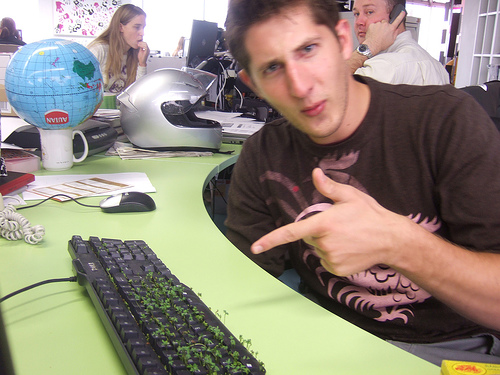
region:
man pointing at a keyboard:
[223, 0, 499, 362]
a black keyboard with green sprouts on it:
[68, 236, 266, 373]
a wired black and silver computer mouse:
[101, 192, 156, 213]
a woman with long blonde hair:
[90, 1, 148, 91]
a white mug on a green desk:
[36, 128, 88, 168]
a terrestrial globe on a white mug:
[3, 36, 105, 128]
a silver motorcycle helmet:
[117, 71, 226, 152]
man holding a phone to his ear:
[351, 0, 406, 43]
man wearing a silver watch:
[356, 43, 373, 59]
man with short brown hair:
[222, 0, 350, 135]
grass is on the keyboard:
[101, 260, 259, 370]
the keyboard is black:
[65, 233, 255, 373]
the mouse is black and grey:
[103, 190, 157, 215]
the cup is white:
[37, 129, 100, 166]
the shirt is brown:
[244, 129, 499, 320]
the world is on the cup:
[0, 32, 104, 123]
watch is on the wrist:
[353, 40, 380, 56]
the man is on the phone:
[363, 3, 450, 80]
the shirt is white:
[376, 43, 461, 87]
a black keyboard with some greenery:
[72, 237, 264, 366]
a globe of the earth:
[5, 39, 107, 128]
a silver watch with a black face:
[355, 40, 372, 56]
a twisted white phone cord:
[0, 205, 41, 245]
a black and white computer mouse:
[100, 190, 157, 212]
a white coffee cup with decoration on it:
[40, 128, 87, 171]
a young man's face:
[236, 0, 355, 135]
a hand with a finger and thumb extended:
[253, 168, 389, 276]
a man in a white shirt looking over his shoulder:
[353, 0, 446, 84]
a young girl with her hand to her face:
[93, 1, 148, 88]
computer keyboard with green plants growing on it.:
[62, 233, 267, 373]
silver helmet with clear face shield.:
[116, 65, 222, 149]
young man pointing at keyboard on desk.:
[222, 1, 497, 363]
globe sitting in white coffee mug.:
[5, 37, 102, 131]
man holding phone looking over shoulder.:
[352, 0, 450, 86]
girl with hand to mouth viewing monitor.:
[87, 3, 149, 94]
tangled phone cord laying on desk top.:
[1, 203, 44, 245]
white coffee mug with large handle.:
[35, 127, 89, 169]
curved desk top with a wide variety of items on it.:
[1, 140, 441, 373]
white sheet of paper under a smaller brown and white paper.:
[21, 170, 156, 204]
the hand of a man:
[248, 165, 388, 280]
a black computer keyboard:
[64, 231, 269, 373]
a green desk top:
[0, 130, 442, 373]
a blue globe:
[0, 39, 110, 129]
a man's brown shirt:
[223, 75, 498, 350]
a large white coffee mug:
[35, 128, 94, 172]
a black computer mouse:
[102, 185, 158, 212]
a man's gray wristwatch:
[357, 40, 372, 59]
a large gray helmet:
[116, 67, 223, 152]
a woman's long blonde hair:
[83, 3, 152, 83]